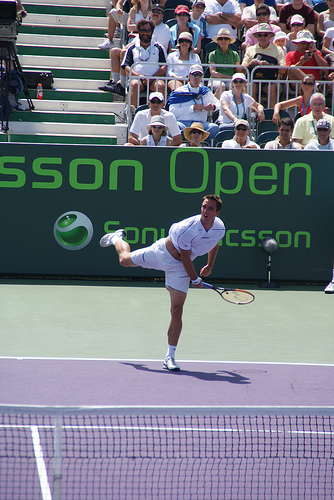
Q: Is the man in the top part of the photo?
A: Yes, the man is in the top of the image.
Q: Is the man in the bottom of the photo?
A: No, the man is in the top of the image.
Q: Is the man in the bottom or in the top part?
A: The man is in the top of the image.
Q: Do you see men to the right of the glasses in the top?
A: Yes, there is a man to the right of the glasses.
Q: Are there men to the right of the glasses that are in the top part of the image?
A: Yes, there is a man to the right of the glasses.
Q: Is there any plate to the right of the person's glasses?
A: No, there is a man to the right of the glasses.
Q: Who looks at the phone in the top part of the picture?
A: The man looks at the telephone.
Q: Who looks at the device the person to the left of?
A: The man looks at the telephone.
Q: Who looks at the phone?
A: The man looks at the telephone.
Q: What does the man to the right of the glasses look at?
A: The man looks at the phone.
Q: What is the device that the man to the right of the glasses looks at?
A: The device is a phone.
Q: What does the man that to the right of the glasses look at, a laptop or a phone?
A: The man looks at a phone.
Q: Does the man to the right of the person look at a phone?
A: Yes, the man looks at a phone.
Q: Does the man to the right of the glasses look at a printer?
A: No, the man looks at a phone.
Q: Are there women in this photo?
A: Yes, there is a woman.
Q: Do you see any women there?
A: Yes, there is a woman.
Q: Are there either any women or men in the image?
A: Yes, there is a woman.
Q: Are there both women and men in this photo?
A: Yes, there are both a woman and a man.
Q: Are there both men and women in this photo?
A: Yes, there are both a woman and a man.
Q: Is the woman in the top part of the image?
A: Yes, the woman is in the top of the image.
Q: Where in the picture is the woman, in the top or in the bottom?
A: The woman is in the top of the image.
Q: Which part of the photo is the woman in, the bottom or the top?
A: The woman is in the top of the image.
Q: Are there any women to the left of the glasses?
A: Yes, there is a woman to the left of the glasses.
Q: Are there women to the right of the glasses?
A: No, the woman is to the left of the glasses.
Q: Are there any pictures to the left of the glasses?
A: No, there is a woman to the left of the glasses.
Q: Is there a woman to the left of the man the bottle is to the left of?
A: No, the woman is to the right of the man.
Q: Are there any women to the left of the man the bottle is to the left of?
A: No, the woman is to the right of the man.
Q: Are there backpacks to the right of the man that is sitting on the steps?
A: No, there is a woman to the right of the man.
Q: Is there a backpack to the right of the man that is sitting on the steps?
A: No, there is a woman to the right of the man.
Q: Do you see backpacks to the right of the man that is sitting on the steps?
A: No, there is a woman to the right of the man.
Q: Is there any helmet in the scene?
A: No, there are no helmets.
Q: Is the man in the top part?
A: Yes, the man is in the top of the image.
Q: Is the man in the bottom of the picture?
A: No, the man is in the top of the image.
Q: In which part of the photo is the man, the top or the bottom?
A: The man is in the top of the image.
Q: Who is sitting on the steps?
A: The man is sitting on the steps.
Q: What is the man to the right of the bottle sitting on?
A: The man is sitting on the steps.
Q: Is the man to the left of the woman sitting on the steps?
A: Yes, the man is sitting on the steps.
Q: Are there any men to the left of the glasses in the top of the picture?
A: Yes, there is a man to the left of the glasses.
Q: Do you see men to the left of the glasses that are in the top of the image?
A: Yes, there is a man to the left of the glasses.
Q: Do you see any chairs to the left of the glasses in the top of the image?
A: No, there is a man to the left of the glasses.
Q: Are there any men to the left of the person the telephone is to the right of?
A: Yes, there is a man to the left of the person.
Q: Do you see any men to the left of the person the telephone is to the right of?
A: Yes, there is a man to the left of the person.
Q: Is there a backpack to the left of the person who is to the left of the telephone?
A: No, there is a man to the left of the person.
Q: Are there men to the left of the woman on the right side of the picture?
A: Yes, there is a man to the left of the woman.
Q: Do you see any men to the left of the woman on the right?
A: Yes, there is a man to the left of the woman.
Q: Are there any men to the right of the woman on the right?
A: No, the man is to the left of the woman.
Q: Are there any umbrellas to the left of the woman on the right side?
A: No, there is a man to the left of the woman.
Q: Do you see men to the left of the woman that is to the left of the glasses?
A: Yes, there is a man to the left of the woman.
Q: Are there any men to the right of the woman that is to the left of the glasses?
A: No, the man is to the left of the woman.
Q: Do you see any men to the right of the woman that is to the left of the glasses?
A: No, the man is to the left of the woman.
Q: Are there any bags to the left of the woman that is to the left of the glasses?
A: No, there is a man to the left of the woman.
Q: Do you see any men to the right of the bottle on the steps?
A: Yes, there is a man to the right of the bottle.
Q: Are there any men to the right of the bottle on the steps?
A: Yes, there is a man to the right of the bottle.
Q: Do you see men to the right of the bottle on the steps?
A: Yes, there is a man to the right of the bottle.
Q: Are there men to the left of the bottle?
A: No, the man is to the right of the bottle.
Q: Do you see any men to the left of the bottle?
A: No, the man is to the right of the bottle.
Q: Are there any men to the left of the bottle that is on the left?
A: No, the man is to the right of the bottle.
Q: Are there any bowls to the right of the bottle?
A: No, there is a man to the right of the bottle.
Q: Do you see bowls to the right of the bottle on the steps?
A: No, there is a man to the right of the bottle.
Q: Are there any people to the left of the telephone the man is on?
A: Yes, there is a person to the left of the telephone.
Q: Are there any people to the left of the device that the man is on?
A: Yes, there is a person to the left of the telephone.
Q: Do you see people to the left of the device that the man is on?
A: Yes, there is a person to the left of the telephone.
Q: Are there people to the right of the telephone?
A: No, the person is to the left of the telephone.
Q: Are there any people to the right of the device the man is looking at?
A: No, the person is to the left of the telephone.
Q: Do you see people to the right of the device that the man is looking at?
A: No, the person is to the left of the telephone.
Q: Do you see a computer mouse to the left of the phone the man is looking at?
A: No, there is a person to the left of the phone.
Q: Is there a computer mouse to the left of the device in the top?
A: No, there is a person to the left of the phone.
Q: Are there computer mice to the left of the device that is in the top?
A: No, there is a person to the left of the phone.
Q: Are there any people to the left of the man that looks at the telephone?
A: Yes, there is a person to the left of the man.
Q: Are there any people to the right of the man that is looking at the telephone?
A: No, the person is to the left of the man.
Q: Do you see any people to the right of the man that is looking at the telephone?
A: No, the person is to the left of the man.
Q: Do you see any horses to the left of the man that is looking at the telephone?
A: No, there is a person to the left of the man.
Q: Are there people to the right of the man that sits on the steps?
A: Yes, there is a person to the right of the man.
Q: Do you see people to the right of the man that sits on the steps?
A: Yes, there is a person to the right of the man.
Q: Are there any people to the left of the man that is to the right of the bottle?
A: No, the person is to the right of the man.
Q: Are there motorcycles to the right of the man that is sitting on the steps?
A: No, there is a person to the right of the man.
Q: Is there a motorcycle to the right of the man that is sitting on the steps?
A: No, there is a person to the right of the man.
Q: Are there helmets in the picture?
A: No, there are no helmets.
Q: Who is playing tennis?
A: The player is playing tennis.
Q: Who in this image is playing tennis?
A: The player is playing tennis.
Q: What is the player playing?
A: The player is playing tennis.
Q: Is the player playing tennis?
A: Yes, the player is playing tennis.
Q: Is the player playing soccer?
A: No, the player is playing tennis.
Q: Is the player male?
A: Yes, the player is male.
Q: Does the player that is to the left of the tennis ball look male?
A: Yes, the player is male.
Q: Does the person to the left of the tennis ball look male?
A: Yes, the player is male.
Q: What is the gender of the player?
A: The player is male.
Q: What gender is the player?
A: The player is male.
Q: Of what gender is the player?
A: The player is male.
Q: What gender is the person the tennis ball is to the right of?
A: The player is male.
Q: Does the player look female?
A: No, the player is male.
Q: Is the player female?
A: No, the player is male.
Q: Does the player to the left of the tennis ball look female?
A: No, the player is male.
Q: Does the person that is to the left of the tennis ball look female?
A: No, the player is male.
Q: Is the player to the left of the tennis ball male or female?
A: The player is male.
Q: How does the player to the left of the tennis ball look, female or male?
A: The player is male.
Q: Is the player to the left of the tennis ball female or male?
A: The player is male.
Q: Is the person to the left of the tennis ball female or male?
A: The player is male.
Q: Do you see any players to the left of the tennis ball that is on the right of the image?
A: Yes, there is a player to the left of the tennis ball.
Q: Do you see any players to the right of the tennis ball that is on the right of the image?
A: No, the player is to the left of the tennis ball.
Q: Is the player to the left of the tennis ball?
A: Yes, the player is to the left of the tennis ball.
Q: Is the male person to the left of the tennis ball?
A: Yes, the player is to the left of the tennis ball.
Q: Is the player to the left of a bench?
A: No, the player is to the left of the tennis ball.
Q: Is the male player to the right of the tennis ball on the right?
A: No, the player is to the left of the tennis ball.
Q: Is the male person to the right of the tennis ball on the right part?
A: No, the player is to the left of the tennis ball.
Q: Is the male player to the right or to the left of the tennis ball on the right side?
A: The player is to the left of the tennis ball.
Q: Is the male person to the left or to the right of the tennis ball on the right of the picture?
A: The player is to the left of the tennis ball.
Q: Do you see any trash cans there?
A: No, there are no trash cans.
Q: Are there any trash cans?
A: No, there are no trash cans.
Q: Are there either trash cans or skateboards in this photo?
A: No, there are no trash cans or skateboards.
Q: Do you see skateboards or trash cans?
A: No, there are no trash cans or skateboards.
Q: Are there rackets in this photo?
A: Yes, there is a racket.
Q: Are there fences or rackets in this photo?
A: Yes, there is a racket.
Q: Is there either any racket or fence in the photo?
A: Yes, there is a racket.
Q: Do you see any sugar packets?
A: No, there are no sugar packets.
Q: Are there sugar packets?
A: No, there are no sugar packets.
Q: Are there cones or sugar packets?
A: No, there are no sugar packets or cones.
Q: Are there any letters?
A: Yes, there are letters.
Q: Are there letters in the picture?
A: Yes, there are letters.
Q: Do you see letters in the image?
A: Yes, there are letters.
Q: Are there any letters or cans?
A: Yes, there are letters.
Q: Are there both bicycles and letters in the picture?
A: No, there are letters but no bikes.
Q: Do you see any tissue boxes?
A: No, there are no tissue boxes.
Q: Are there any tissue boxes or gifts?
A: No, there are no tissue boxes or gifts.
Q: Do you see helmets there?
A: No, there are no helmets.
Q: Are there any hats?
A: Yes, there is a hat.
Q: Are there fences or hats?
A: Yes, there is a hat.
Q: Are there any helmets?
A: No, there are no helmets.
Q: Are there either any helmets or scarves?
A: No, there are no helmets or scarves.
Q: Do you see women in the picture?
A: Yes, there is a woman.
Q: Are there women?
A: Yes, there is a woman.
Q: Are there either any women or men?
A: Yes, there is a woman.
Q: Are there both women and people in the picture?
A: Yes, there are both a woman and a person.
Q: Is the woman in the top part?
A: Yes, the woman is in the top of the image.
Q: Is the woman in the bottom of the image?
A: No, the woman is in the top of the image.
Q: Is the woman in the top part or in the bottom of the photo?
A: The woman is in the top of the image.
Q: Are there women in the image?
A: Yes, there is a woman.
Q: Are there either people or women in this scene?
A: Yes, there is a woman.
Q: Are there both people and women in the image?
A: Yes, there are both a woman and a person.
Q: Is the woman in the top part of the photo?
A: Yes, the woman is in the top of the image.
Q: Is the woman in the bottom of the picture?
A: No, the woman is in the top of the image.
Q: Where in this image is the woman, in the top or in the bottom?
A: The woman is in the top of the image.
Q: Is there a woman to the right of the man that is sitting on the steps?
A: Yes, there is a woman to the right of the man.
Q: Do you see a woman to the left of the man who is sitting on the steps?
A: No, the woman is to the right of the man.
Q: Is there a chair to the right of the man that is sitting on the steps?
A: No, there is a woman to the right of the man.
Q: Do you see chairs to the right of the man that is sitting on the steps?
A: No, there is a woman to the right of the man.